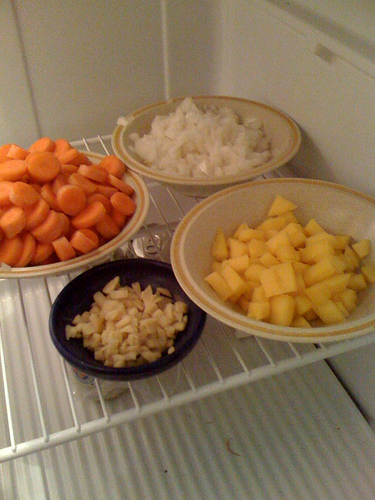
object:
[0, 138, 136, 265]
carrots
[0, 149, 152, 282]
bowl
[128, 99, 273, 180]
onions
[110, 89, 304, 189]
bowl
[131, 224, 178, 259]
can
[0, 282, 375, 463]
bottom shelf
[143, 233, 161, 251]
tab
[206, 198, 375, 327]
pineapples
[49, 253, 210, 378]
bowl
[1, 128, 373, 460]
shelf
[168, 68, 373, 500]
right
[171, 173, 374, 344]
bowl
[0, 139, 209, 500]
left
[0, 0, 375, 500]
refrigerator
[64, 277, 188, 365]
nuts